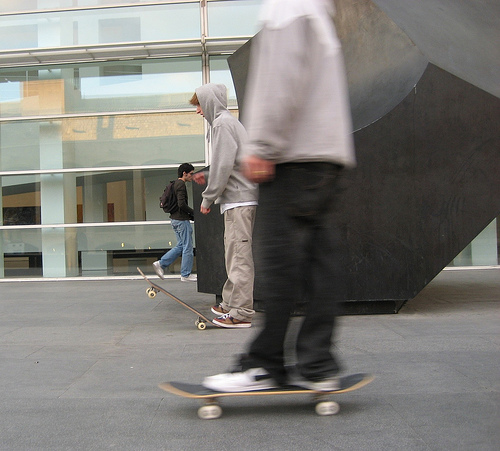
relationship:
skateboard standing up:
[132, 260, 215, 330] [136, 276, 180, 332]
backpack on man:
[152, 176, 179, 219] [153, 158, 193, 283]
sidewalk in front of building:
[0, 274, 500, 449] [2, 2, 499, 274]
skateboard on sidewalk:
[132, 260, 215, 330] [0, 274, 500, 449]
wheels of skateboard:
[145, 283, 159, 299] [132, 260, 215, 330]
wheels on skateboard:
[145, 283, 159, 299] [132, 260, 215, 330]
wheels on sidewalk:
[145, 283, 159, 299] [0, 274, 500, 449]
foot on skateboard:
[210, 311, 261, 328] [132, 260, 215, 330]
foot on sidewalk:
[210, 311, 261, 328] [0, 274, 500, 449]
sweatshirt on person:
[197, 79, 262, 210] [202, 18, 348, 391]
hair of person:
[190, 92, 202, 111] [202, 18, 348, 391]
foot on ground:
[210, 311, 261, 328] [0, 274, 500, 449]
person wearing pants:
[202, 18, 348, 391] [237, 159, 352, 387]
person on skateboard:
[202, 18, 348, 391] [132, 260, 215, 330]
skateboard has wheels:
[132, 260, 215, 330] [145, 283, 159, 299]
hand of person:
[245, 153, 275, 192] [202, 18, 348, 391]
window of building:
[64, 109, 211, 169] [2, 2, 499, 274]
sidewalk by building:
[0, 274, 500, 449] [2, 2, 499, 274]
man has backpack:
[153, 158, 193, 283] [152, 176, 179, 219]